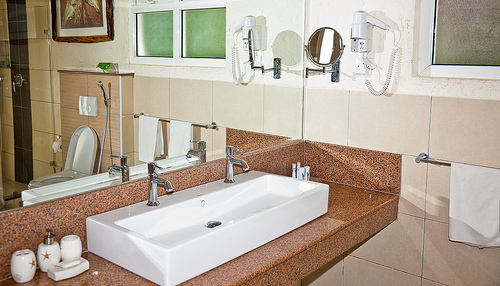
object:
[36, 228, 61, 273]
dispenser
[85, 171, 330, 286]
sink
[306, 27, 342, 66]
mirror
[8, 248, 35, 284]
holder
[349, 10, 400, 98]
hair dryer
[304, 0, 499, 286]
wall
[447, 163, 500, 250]
towel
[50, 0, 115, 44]
frame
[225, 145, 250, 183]
faucet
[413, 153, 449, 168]
rack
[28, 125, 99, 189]
toilet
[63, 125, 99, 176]
lid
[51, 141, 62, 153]
toilet paper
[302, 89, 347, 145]
tile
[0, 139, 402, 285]
counter top